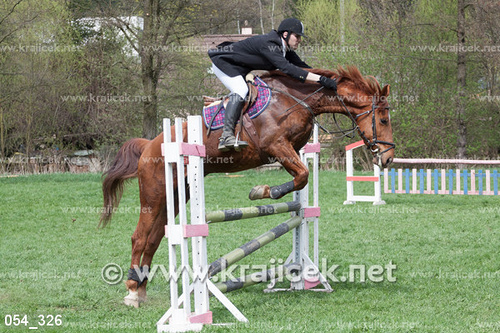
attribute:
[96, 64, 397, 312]
horse — brown, jumping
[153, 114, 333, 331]
gate — white, pink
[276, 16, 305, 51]
cap — black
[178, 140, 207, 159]
board — pink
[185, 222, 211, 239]
board — pink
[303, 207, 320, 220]
board — pink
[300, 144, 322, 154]
board — pink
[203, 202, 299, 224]
obstacle bar — lime, gray, green, purple, striped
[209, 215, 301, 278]
obstacle bar — lime, gray, green, purple, striped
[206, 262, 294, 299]
obstacle bar — lime, gray, green, purple, striped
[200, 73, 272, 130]
saddle — pink, purple, red, blue, plaid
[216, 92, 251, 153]
boots — black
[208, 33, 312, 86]
jacket — black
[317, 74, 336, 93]
glove — black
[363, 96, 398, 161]
bridle — black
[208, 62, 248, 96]
pants — white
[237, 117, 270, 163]
saddle strap — leather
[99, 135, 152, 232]
tail — brown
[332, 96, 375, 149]
reign — black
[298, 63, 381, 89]
mane — brown